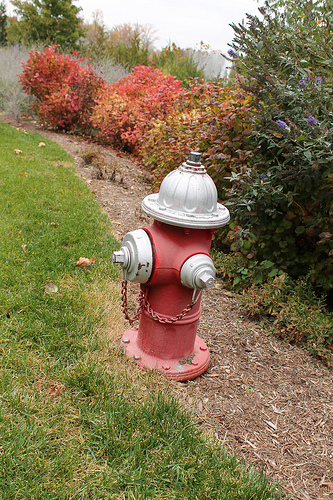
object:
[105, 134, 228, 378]
hydrant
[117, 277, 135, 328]
chains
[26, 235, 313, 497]
ground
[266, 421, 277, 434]
wood chips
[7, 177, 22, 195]
grass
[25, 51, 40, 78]
bushes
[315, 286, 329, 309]
bush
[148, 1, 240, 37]
sky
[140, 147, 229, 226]
cap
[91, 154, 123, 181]
mulch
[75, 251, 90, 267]
leaf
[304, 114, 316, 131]
flowers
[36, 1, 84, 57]
tree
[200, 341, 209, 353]
bolts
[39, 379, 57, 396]
hay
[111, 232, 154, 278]
knob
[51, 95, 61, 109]
leaves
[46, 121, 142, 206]
path